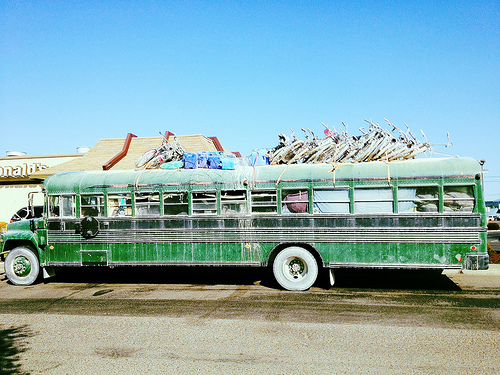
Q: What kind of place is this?
A: It is a street.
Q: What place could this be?
A: It is a street.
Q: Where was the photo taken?
A: It was taken at the street.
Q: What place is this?
A: It is a street.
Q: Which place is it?
A: It is a street.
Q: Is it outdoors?
A: Yes, it is outdoors.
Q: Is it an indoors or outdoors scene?
A: It is outdoors.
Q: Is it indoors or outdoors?
A: It is outdoors.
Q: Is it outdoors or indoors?
A: It is outdoors.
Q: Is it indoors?
A: No, it is outdoors.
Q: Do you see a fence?
A: No, there are no fences.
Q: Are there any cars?
A: No, there are no cars.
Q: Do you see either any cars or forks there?
A: No, there are no cars or forks.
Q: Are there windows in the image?
A: Yes, there is a window.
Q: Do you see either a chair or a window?
A: Yes, there is a window.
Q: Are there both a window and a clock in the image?
A: No, there is a window but no clocks.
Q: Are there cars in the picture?
A: No, there are no cars.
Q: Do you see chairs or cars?
A: No, there are no cars or chairs.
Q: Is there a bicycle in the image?
A: Yes, there are bicycles.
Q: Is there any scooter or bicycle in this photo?
A: Yes, there are bicycles.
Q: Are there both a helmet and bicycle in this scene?
A: No, there are bicycles but no helmets.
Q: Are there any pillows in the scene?
A: No, there are no pillows.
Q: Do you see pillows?
A: No, there are no pillows.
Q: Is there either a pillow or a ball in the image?
A: No, there are no pillows or balls.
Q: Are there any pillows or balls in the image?
A: No, there are no pillows or balls.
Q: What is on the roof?
A: The bicycles are on the roof.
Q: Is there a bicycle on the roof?
A: Yes, there are bicycles on the roof.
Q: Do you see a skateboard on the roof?
A: No, there are bicycles on the roof.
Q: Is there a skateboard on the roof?
A: No, there are bicycles on the roof.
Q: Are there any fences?
A: No, there are no fences.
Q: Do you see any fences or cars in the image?
A: No, there are no fences or cars.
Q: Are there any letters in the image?
A: Yes, there are letters.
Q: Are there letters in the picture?
A: Yes, there are letters.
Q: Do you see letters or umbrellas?
A: Yes, there are letters.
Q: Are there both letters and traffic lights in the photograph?
A: No, there are letters but no traffic lights.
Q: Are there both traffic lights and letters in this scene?
A: No, there are letters but no traffic lights.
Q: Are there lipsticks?
A: No, there are no lipsticks.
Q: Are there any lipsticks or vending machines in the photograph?
A: No, there are no lipsticks or vending machines.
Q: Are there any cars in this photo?
A: No, there are no cars.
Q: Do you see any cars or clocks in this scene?
A: No, there are no cars or clocks.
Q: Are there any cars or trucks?
A: No, there are no cars or trucks.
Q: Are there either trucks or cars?
A: No, there are no cars or trucks.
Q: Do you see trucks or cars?
A: No, there are no cars or trucks.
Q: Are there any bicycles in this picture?
A: Yes, there are bicycles.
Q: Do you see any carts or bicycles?
A: Yes, there are bicycles.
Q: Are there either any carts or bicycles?
A: Yes, there are bicycles.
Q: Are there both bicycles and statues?
A: No, there are bicycles but no statues.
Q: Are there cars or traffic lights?
A: No, there are no cars or traffic lights.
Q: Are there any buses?
A: Yes, there is a bus.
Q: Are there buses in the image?
A: Yes, there is a bus.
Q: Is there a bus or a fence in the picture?
A: Yes, there is a bus.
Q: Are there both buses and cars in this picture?
A: No, there is a bus but no cars.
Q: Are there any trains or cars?
A: No, there are no cars or trains.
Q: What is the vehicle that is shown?
A: The vehicle is a bus.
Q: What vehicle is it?
A: The vehicle is a bus.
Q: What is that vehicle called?
A: That is a bus.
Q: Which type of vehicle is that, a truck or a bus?
A: That is a bus.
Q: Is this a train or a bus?
A: This is a bus.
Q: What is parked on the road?
A: The bus is parked on the road.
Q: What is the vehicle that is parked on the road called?
A: The vehicle is a bus.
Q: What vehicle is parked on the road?
A: The vehicle is a bus.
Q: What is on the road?
A: The bus is on the road.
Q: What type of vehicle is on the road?
A: The vehicle is a bus.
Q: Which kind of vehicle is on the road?
A: The vehicle is a bus.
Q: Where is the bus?
A: The bus is on the road.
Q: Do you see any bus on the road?
A: Yes, there is a bus on the road.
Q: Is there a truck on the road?
A: No, there is a bus on the road.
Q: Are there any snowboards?
A: Yes, there is a snowboard.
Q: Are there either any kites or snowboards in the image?
A: Yes, there is a snowboard.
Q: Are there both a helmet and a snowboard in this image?
A: No, there is a snowboard but no helmets.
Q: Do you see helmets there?
A: No, there are no helmets.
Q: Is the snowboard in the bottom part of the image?
A: Yes, the snowboard is in the bottom of the image.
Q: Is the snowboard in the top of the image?
A: No, the snowboard is in the bottom of the image.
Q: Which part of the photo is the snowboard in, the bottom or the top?
A: The snowboard is in the bottom of the image.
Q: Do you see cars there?
A: No, there are no cars.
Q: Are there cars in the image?
A: No, there are no cars.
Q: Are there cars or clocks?
A: No, there are no cars or clocks.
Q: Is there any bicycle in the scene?
A: Yes, there is a bicycle.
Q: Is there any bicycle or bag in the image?
A: Yes, there is a bicycle.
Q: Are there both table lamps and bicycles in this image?
A: No, there is a bicycle but no table lamps.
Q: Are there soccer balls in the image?
A: No, there are no soccer balls.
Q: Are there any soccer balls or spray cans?
A: No, there are no soccer balls or spray cans.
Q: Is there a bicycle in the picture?
A: Yes, there is a bicycle.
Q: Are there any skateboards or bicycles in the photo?
A: Yes, there is a bicycle.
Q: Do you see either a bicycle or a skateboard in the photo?
A: Yes, there is a bicycle.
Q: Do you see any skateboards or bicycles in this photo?
A: Yes, there is a bicycle.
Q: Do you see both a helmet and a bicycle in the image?
A: No, there is a bicycle but no helmets.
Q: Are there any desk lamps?
A: No, there are no desk lamps.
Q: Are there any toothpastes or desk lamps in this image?
A: No, there are no desk lamps or toothpastes.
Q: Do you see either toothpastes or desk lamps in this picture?
A: No, there are no desk lamps or toothpastes.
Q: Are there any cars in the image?
A: No, there are no cars.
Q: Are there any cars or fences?
A: No, there are no cars or fences.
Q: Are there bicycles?
A: Yes, there is a bicycle.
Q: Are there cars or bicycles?
A: Yes, there is a bicycle.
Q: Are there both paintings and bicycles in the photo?
A: No, there is a bicycle but no paintings.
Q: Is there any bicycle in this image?
A: Yes, there is a bicycle.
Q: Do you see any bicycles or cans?
A: Yes, there is a bicycle.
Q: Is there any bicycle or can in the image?
A: Yes, there is a bicycle.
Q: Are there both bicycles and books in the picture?
A: No, there is a bicycle but no books.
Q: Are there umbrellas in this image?
A: No, there are no umbrellas.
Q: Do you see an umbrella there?
A: No, there are no umbrellas.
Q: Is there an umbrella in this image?
A: No, there are no umbrellas.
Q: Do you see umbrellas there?
A: No, there are no umbrellas.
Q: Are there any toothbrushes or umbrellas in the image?
A: No, there are no umbrellas or toothbrushes.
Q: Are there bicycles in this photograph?
A: Yes, there is a bicycle.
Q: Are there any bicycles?
A: Yes, there is a bicycle.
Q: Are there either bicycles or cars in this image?
A: Yes, there is a bicycle.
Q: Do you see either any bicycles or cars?
A: Yes, there is a bicycle.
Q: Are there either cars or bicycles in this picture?
A: Yes, there is a bicycle.